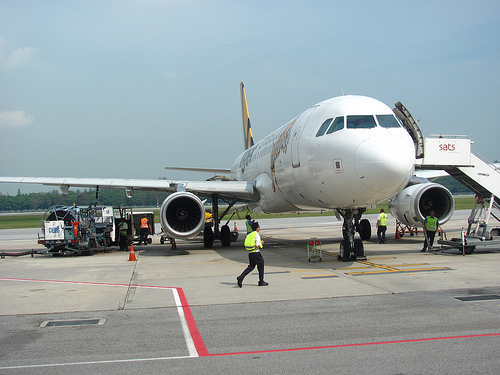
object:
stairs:
[440, 135, 497, 195]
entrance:
[394, 101, 427, 159]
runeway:
[8, 246, 493, 361]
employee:
[415, 211, 438, 253]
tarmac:
[363, 272, 498, 335]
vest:
[242, 230, 260, 252]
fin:
[239, 80, 254, 150]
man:
[228, 208, 270, 294]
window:
[341, 110, 379, 132]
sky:
[2, 1, 497, 85]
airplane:
[0, 93, 500, 254]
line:
[174, 287, 208, 366]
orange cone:
[123, 245, 151, 263]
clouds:
[4, 34, 277, 74]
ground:
[5, 286, 484, 363]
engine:
[161, 185, 208, 240]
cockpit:
[319, 111, 407, 135]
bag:
[241, 230, 262, 250]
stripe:
[119, 248, 136, 258]